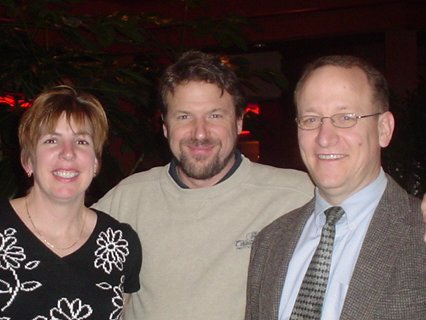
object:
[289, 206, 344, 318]
tie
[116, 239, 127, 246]
petal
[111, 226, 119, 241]
petal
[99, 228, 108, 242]
petal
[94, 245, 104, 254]
petal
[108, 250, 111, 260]
petal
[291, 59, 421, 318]
man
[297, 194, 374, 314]
dress shirt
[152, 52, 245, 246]
man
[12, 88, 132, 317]
woman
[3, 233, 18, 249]
petal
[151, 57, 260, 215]
man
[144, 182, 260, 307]
sweater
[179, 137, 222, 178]
beard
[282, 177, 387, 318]
shirt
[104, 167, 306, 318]
shirt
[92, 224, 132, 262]
flower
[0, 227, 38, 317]
flower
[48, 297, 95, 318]
flower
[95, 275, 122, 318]
flower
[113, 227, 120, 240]
petal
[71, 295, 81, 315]
petal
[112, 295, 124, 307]
petal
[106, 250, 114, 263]
petal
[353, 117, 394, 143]
ground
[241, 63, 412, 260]
man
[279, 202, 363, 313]
tie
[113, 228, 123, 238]
petal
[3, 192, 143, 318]
shirt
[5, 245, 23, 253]
petal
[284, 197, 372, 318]
tie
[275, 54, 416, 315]
man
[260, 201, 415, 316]
gray jacket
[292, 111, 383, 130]
eyeglasses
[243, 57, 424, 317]
person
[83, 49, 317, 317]
person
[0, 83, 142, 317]
person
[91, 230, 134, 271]
flower petal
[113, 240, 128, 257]
petal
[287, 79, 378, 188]
face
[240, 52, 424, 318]
man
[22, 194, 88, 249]
necklace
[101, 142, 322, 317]
shirt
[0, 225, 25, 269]
flowers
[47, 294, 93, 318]
flowers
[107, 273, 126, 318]
flowers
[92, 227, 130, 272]
flowers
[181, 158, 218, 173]
hair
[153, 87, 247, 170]
face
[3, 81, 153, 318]
woman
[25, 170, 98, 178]
earrings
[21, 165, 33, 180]
window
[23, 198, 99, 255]
necklace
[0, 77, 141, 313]
lady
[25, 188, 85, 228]
neck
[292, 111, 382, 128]
glasses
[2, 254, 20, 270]
flower petal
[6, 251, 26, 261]
flower petal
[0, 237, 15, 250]
flower petal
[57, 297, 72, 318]
flower petal